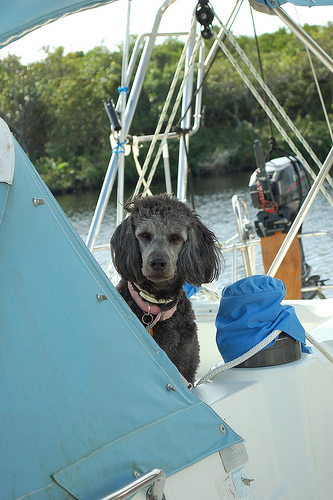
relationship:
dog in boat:
[112, 191, 215, 384] [2, 1, 327, 498]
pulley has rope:
[196, 0, 214, 39] [184, 3, 235, 61]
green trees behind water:
[1, 20, 332, 196] [93, 189, 320, 277]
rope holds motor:
[245, 0, 311, 205] [246, 137, 314, 229]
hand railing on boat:
[96, 465, 167, 499] [2, 1, 327, 498]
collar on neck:
[128, 281, 172, 316] [126, 273, 186, 303]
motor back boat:
[244, 132, 309, 236] [53, 166, 329, 451]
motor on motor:
[248, 154, 311, 238] [235, 128, 316, 242]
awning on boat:
[0, 0, 120, 53] [2, 1, 327, 498]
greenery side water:
[0, 25, 330, 167] [79, 193, 332, 292]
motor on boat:
[248, 154, 311, 238] [2, 1, 327, 498]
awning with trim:
[0, 0, 120, 53] [0, 3, 104, 45]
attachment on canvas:
[31, 197, 45, 206] [0, 114, 247, 498]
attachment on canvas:
[95, 290, 109, 303] [0, 114, 247, 498]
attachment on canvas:
[165, 378, 181, 392] [0, 114, 247, 498]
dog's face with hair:
[132, 211, 190, 281] [135, 214, 183, 281]